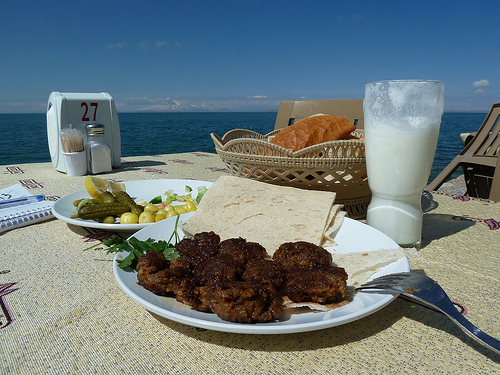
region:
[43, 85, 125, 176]
Napkin holder with the number 27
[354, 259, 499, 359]
Silver fork face down on plate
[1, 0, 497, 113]
Clearblue sky with few clouds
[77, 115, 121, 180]
Glass salt shaker with chrome top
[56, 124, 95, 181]
White container holding toothpicks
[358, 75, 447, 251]
Ornamental glass with white drink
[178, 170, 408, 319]
Pita flat bread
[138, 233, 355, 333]
Meatballs to be used with pita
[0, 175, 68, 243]
Notepad with pen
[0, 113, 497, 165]
Clear blue ocean water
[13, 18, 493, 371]
a seaside restaurant with a set table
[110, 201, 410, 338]
a white ceramic plate is on the table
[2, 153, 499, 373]
a tablecloth is on the table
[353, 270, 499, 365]
a fork is upside down on the plate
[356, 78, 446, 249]
a glass has a frothy white mixture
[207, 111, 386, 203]
a bread basket has bread in it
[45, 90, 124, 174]
toothpicks and salt are next to the napkins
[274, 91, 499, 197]
tan plastic chairs are in the restaurant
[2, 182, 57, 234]
a notebook and a pen is on the table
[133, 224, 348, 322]
fried meat balls are on the plate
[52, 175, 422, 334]
The plates are the color white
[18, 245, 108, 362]
The table cloth is beige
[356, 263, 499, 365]
The fork is the color silver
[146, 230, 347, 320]
The meat on the plate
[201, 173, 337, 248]
The bread is made of flour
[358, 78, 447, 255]
The glass of milk on the table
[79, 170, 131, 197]
The lemon on the plate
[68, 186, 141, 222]
The pickles on the plate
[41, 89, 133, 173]
The napkin holder on the table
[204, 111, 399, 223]
The bowl of bread on the table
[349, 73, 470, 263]
a glass with white liquid in it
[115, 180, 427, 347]
a white plate with food on it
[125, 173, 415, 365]
a white plate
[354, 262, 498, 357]
a silver fork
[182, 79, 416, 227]
a tan basket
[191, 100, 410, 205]
a tan basket with bread in it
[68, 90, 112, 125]
the number 27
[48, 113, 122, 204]
a salt shaker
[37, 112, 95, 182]
a cup of tooth picks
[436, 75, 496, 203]
a brown chair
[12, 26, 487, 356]
meal on table overlooking ocean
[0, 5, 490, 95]
blue sky with a few tiny clouds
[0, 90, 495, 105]
land on other side of water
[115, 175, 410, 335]
browned pieces of meat with flat bread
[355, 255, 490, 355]
upside down fork resting on edge of plate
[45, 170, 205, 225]
lemon wedge, small pickles and yellow beans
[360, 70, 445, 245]
frothy white drink in tall glass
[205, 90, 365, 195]
woven basket with brown loaf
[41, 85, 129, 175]
numbered napkin holder with salt and toothpicks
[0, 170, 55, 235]
spiral notebook with pen